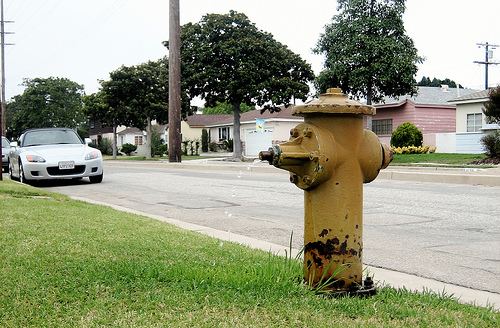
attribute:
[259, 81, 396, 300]
fire hydrant — beige, yellow, older, rusting, old, painted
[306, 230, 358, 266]
rust — brown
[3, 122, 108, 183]
sports car — parked, silver, white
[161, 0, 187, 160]
pole — wood, distant, wooden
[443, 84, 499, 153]
house — white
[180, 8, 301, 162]
tree — tall, green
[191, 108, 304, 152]
house — yellow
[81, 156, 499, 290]
street — pavement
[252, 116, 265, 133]
flag — blue